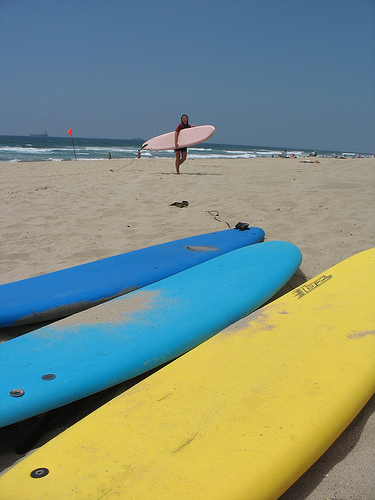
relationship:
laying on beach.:
[0, 246, 374, 500] [0, 155, 373, 500]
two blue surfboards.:
[0, 226, 304, 430] [1, 226, 301, 428]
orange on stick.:
[65, 127, 75, 141] [64, 125, 78, 161]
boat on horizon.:
[26, 131, 51, 139] [0, 129, 374, 156]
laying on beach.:
[297, 158, 322, 166] [0, 155, 373, 500]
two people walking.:
[105, 146, 147, 163] [106, 148, 144, 162]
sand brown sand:
[0, 155, 373, 498] [0, 155, 373, 308]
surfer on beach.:
[137, 113, 215, 175] [0, 155, 373, 500]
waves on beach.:
[0, 144, 374, 168] [0, 155, 373, 500]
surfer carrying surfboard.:
[175, 114, 195, 173] [139, 125, 216, 152]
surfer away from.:
[175, 114, 195, 173] [1, 135, 374, 167]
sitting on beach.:
[270, 148, 373, 164] [0, 155, 373, 500]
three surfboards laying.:
[2, 226, 373, 500] [0, 246, 374, 500]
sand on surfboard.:
[48, 291, 159, 326] [1, 240, 301, 429]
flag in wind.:
[65, 127, 75, 141] [1, 1, 374, 162]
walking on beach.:
[106, 148, 144, 162] [0, 155, 373, 500]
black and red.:
[172, 114, 193, 174] [174, 112, 192, 174]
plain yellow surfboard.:
[1, 246, 373, 500] [1, 246, 374, 498]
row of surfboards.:
[1, 226, 374, 499] [2, 226, 375, 500]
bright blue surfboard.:
[1, 241, 301, 428] [1, 240, 301, 429]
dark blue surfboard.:
[0, 227, 266, 325] [0, 225, 266, 330]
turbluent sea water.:
[1, 133, 374, 164] [1, 134, 374, 162]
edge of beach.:
[2, 151, 373, 167] [0, 155, 373, 500]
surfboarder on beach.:
[137, 113, 215, 175] [0, 155, 373, 500]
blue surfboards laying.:
[0, 226, 304, 430] [2, 226, 301, 428]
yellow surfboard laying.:
[1, 246, 374, 498] [0, 246, 374, 500]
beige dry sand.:
[2, 155, 373, 500] [0, 156, 374, 499]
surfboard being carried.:
[140, 123, 215, 152] [137, 113, 215, 175]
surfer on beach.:
[175, 114, 195, 173] [0, 155, 373, 500]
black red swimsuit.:
[172, 114, 193, 174] [173, 114, 194, 175]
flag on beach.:
[64, 128, 78, 162] [0, 155, 373, 500]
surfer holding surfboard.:
[175, 114, 195, 173] [139, 125, 216, 152]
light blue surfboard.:
[0, 240, 304, 426] [1, 240, 301, 429]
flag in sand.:
[64, 128, 78, 162] [0, 156, 374, 499]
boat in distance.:
[26, 131, 51, 139] [0, 129, 374, 156]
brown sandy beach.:
[1, 154, 374, 499] [0, 155, 373, 500]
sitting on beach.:
[267, 148, 374, 160] [0, 155, 373, 500]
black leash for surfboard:
[107, 143, 151, 174] [65, 231, 359, 466]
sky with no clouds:
[103, 41, 176, 90] [245, 9, 311, 66]